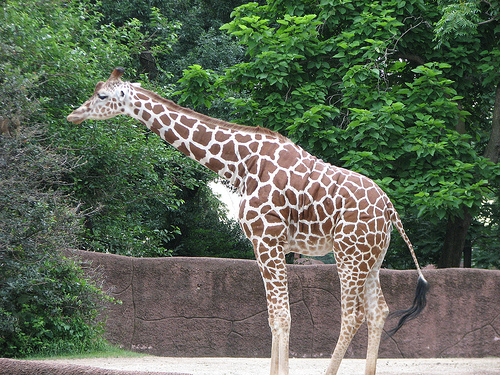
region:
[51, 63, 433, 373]
giraffe is brown and white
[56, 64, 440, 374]
giraffe is in enclosure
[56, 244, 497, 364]
stone wall behind giraffe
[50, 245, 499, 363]
stone wall is dark brown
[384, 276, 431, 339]
black hair hanging from tail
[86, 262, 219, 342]
cracks in the wall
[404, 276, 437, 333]
the hair is black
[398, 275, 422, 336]
the hair is long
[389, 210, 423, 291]
the tail is thin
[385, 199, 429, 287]
the tail is spotted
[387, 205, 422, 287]
the tail is long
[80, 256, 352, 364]
the wall is stone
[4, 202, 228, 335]
bush is by the wall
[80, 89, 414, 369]
the giraffe is spotted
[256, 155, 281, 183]
upside down heart shaped brown spot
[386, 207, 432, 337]
stiff tail with tuft of black hair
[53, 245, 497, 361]
low brown concrete wall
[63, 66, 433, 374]
tall giraffe leaning toward tree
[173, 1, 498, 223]
bright green tree with large foliage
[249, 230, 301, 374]
long front leg of giraffe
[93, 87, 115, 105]
large closed eye of giraffe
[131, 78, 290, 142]
long stiff brown mane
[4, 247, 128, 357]
short dark green bush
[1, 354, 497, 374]
light brown dirt ground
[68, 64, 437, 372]
tall giraffe grazing on leaves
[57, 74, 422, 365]
giraffe with long legs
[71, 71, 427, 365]
giraffe has a long neck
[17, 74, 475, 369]
giraffe is in an enclosure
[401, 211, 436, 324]
giraffe has skinny short tail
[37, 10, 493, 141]
trees and bushes around giraffe enclosure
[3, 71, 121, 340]
bushes near giraffe habitat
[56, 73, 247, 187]
giraffe has long neck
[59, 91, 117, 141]
Nose on a zebra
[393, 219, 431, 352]
Tail on a zebra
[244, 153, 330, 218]
Spots on a zebra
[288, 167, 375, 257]
Brown spots on a zebra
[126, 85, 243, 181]
Neck on a zebra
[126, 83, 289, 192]
Spots on a zebra's neck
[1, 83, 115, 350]
Green bush by a zebra's head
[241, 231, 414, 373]
Four legs on a zebra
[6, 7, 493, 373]
a scene at a zoo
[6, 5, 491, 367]
a scene during the day time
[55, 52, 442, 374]
a giraffe standing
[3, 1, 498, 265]
green trees in the background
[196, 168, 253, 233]
a white sky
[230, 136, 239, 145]
a spot on the animal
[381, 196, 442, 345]
Tail of a giraffe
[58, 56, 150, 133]
Head of a giraffe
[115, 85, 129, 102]
Ear of a giraffe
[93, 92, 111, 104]
Eye of a giraffe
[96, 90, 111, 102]
Black colored eye of a giraffe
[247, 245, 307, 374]
Front legs of a giraffe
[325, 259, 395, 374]
Back legs of a giraffe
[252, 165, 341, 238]
Midsection of a giraffe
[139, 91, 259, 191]
Neck of a giraffe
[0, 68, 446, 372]
a giraffe eating a tree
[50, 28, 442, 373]
a girffe eating a tree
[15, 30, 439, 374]
a giraffe is eating a leave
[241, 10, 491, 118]
a bunch of green leaves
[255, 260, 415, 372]
legs on the giraffe